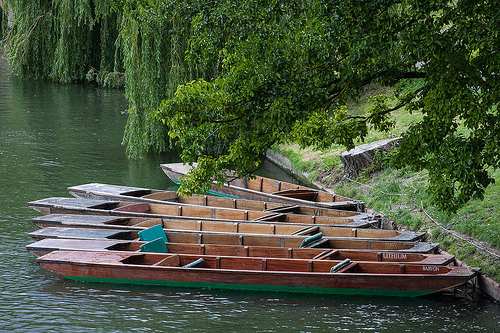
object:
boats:
[156, 152, 369, 213]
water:
[1, 73, 176, 332]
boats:
[64, 176, 385, 225]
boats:
[24, 190, 385, 232]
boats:
[28, 208, 426, 243]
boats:
[21, 222, 440, 255]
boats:
[20, 233, 460, 268]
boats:
[28, 248, 484, 298]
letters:
[418, 263, 443, 275]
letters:
[380, 249, 412, 261]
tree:
[116, 2, 232, 162]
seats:
[141, 236, 174, 256]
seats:
[135, 220, 173, 246]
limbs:
[299, 80, 425, 140]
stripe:
[61, 274, 438, 297]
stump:
[333, 133, 411, 175]